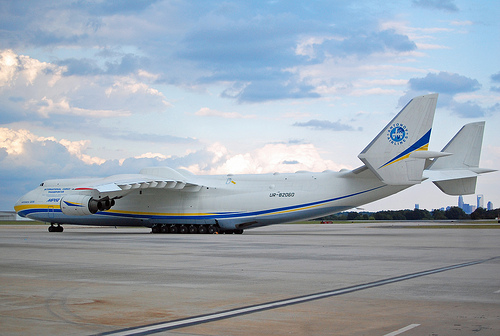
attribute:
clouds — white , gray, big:
[205, 139, 332, 169]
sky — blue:
[0, 2, 499, 222]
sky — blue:
[178, 16, 412, 124]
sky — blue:
[243, 116, 287, 142]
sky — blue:
[1, 2, 498, 199]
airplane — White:
[13, 92, 497, 234]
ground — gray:
[283, 113, 328, 166]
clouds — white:
[5, 45, 157, 141]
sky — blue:
[164, 35, 323, 110]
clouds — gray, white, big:
[35, 6, 371, 105]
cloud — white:
[0, 49, 178, 128]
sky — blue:
[326, 20, 408, 75]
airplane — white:
[62, 117, 493, 265]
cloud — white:
[386, 19, 463, 54]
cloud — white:
[213, 139, 349, 176]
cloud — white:
[37, 77, 174, 119]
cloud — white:
[0, 45, 67, 84]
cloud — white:
[0, 126, 105, 164]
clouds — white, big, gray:
[1, 48, 171, 123]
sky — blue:
[157, 98, 270, 129]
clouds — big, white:
[74, 67, 244, 137]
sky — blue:
[158, 67, 284, 104]